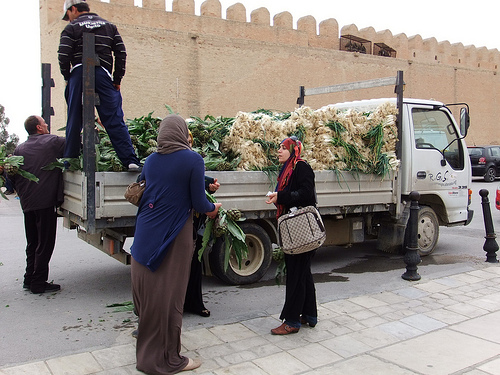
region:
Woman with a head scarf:
[261, 134, 327, 353]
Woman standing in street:
[264, 131, 328, 356]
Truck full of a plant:
[24, 62, 481, 279]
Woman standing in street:
[119, 106, 215, 370]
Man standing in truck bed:
[50, 1, 150, 190]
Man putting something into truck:
[7, 111, 99, 314]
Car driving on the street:
[461, 139, 498, 183]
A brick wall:
[37, 0, 497, 145]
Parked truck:
[36, 61, 497, 276]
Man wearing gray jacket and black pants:
[7, 110, 82, 330]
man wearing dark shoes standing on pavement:
[10, 108, 89, 318]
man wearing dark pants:
[15, 107, 77, 284]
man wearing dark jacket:
[8, 111, 70, 206]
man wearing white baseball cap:
[44, 1, 142, 113]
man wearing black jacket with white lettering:
[29, 16, 184, 107]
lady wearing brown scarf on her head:
[92, 102, 214, 372]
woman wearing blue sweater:
[107, 131, 231, 297]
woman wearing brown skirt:
[104, 236, 234, 374]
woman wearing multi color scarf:
[264, 130, 348, 355]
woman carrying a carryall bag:
[246, 107, 333, 369]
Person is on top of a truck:
[56, 2, 158, 182]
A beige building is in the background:
[40, 1, 497, 133]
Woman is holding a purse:
[254, 121, 330, 262]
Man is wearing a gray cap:
[42, 1, 152, 82]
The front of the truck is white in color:
[365, 81, 487, 242]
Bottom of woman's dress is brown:
[121, 251, 218, 373]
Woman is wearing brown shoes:
[255, 300, 322, 349]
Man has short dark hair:
[12, 111, 54, 145]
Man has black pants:
[13, 205, 71, 299]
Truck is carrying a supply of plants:
[101, 97, 400, 172]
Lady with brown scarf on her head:
[148, 110, 189, 151]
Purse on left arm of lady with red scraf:
[271, 202, 331, 257]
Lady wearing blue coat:
[130, 145, 215, 325]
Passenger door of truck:
[405, 87, 475, 222]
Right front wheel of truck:
[402, 200, 447, 261]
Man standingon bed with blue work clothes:
[60, 0, 137, 177]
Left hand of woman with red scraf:
[260, 185, 280, 201]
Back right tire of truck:
[215, 216, 275, 282]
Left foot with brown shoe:
[265, 310, 310, 340]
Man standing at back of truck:
[5, 105, 71, 310]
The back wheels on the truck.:
[210, 222, 285, 287]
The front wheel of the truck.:
[408, 198, 440, 256]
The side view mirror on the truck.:
[444, 105, 470, 140]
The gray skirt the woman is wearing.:
[130, 210, 201, 372]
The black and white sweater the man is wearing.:
[54, 13, 131, 70]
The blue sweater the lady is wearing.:
[127, 152, 215, 248]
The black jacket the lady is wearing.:
[276, 167, 318, 212]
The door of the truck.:
[409, 110, 471, 210]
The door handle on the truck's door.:
[414, 160, 430, 183]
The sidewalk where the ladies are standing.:
[17, 267, 499, 373]